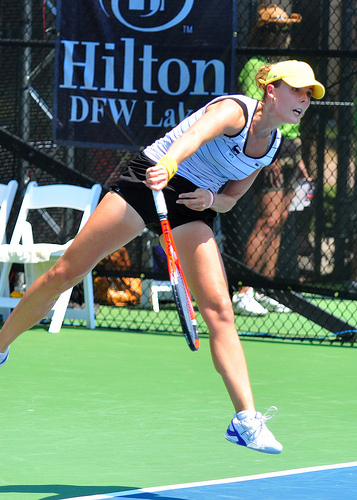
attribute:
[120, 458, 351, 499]
tennis court — blue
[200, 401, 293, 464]
purple shoe — white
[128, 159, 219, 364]
orange racket — used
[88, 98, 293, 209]
black striped shirt — white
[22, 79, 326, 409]
woman — wearing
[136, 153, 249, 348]
hockey stick — red, black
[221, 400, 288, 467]
white sneakers — blue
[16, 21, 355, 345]
wire mesh — black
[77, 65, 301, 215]
stripped vest — striped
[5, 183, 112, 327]
folding chair — white, wooden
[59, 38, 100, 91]
letter — large, white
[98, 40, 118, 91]
letter — large, white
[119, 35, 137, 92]
letter — large, white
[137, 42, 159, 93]
letter — large, white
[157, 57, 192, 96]
letter — large, white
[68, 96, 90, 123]
letter — white, large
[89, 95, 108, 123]
letter — white, large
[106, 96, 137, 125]
letter — white, large